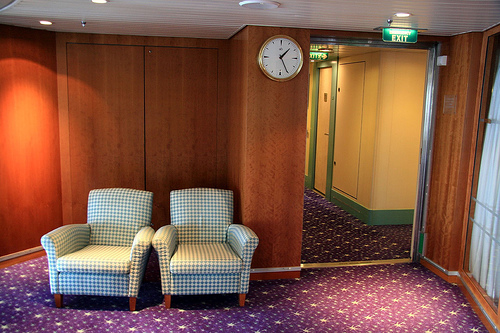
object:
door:
[431, 21, 500, 333]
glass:
[467, 34, 498, 304]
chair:
[41, 187, 156, 311]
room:
[1, 1, 499, 332]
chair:
[151, 187, 260, 308]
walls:
[0, 24, 482, 283]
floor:
[0, 186, 488, 332]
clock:
[257, 34, 305, 83]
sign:
[381, 28, 417, 44]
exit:
[392, 35, 408, 42]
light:
[0, 57, 59, 241]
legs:
[54, 294, 66, 307]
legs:
[164, 294, 174, 308]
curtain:
[467, 63, 499, 300]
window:
[458, 21, 500, 332]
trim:
[258, 34, 304, 82]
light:
[39, 19, 52, 26]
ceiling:
[1, 0, 498, 41]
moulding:
[312, 37, 439, 265]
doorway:
[302, 33, 429, 270]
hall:
[303, 42, 432, 263]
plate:
[442, 95, 458, 112]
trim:
[301, 258, 413, 269]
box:
[436, 56, 448, 66]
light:
[93, 0, 109, 5]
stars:
[295, 312, 302, 315]